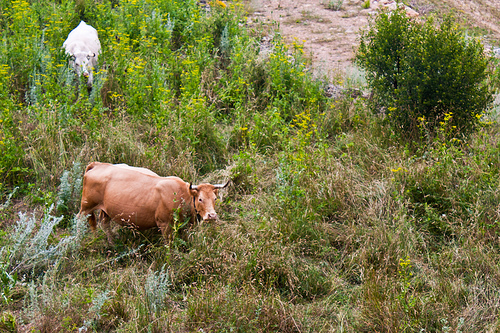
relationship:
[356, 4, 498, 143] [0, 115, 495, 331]
bush on grass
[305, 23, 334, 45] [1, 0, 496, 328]
rocks on ground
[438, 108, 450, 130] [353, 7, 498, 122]
yellow plant in bush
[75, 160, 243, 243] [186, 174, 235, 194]
cow has horns